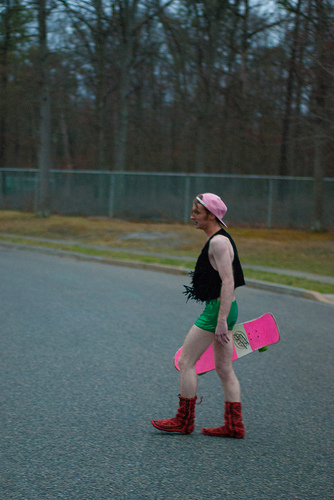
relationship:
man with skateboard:
[165, 188, 260, 449] [167, 336, 279, 369]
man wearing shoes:
[165, 188, 260, 449] [173, 386, 257, 453]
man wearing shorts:
[165, 188, 260, 449] [187, 286, 235, 328]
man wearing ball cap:
[165, 188, 260, 449] [191, 182, 229, 228]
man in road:
[165, 188, 260, 449] [49, 379, 85, 432]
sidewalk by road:
[282, 251, 312, 285] [49, 379, 85, 432]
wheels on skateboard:
[262, 341, 272, 354] [167, 336, 279, 369]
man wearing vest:
[165, 188, 260, 449] [189, 229, 270, 294]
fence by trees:
[267, 184, 305, 211] [175, 55, 244, 102]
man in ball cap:
[165, 188, 260, 449] [191, 182, 229, 228]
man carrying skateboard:
[165, 188, 260, 449] [167, 336, 279, 369]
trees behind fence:
[175, 55, 244, 102] [267, 184, 305, 211]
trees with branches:
[175, 55, 244, 102] [251, 17, 292, 51]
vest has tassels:
[189, 229, 270, 294] [163, 275, 194, 302]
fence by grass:
[267, 184, 305, 211] [265, 236, 316, 275]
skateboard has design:
[167, 336, 279, 369] [228, 335, 247, 347]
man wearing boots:
[165, 188, 260, 449] [153, 390, 239, 450]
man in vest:
[165, 188, 260, 449] [189, 229, 270, 294]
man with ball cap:
[165, 188, 260, 449] [191, 182, 229, 228]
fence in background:
[267, 184, 305, 211] [163, 29, 192, 63]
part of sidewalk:
[124, 221, 162, 246] [282, 251, 312, 285]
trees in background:
[175, 55, 244, 102] [163, 29, 192, 63]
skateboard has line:
[167, 336, 279, 369] [229, 323, 255, 349]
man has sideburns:
[165, 188, 260, 449] [201, 209, 215, 229]